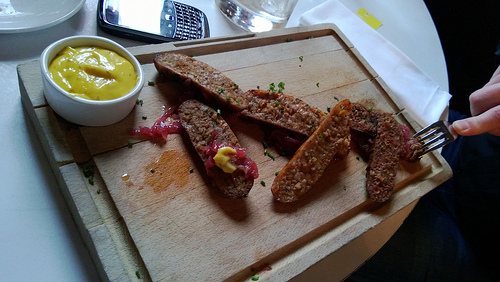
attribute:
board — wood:
[135, 154, 240, 254]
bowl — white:
[38, 34, 144, 131]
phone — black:
[90, 4, 220, 53]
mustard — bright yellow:
[84, 65, 111, 90]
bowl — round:
[37, 20, 152, 149]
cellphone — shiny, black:
[94, 0, 210, 44]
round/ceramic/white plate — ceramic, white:
[1, 0, 88, 37]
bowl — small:
[23, 32, 144, 116]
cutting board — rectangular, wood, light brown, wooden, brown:
[34, 34, 457, 277]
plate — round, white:
[1, 1, 88, 34]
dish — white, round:
[34, 37, 167, 122]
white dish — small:
[36, 22, 144, 127]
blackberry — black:
[94, 1, 212, 43]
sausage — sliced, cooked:
[153, 50, 420, 213]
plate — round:
[1, 0, 91, 40]